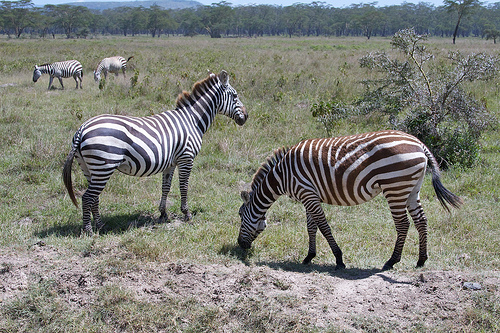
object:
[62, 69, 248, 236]
zebra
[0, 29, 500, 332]
field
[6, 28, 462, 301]
scenery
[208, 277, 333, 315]
dirt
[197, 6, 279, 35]
tree